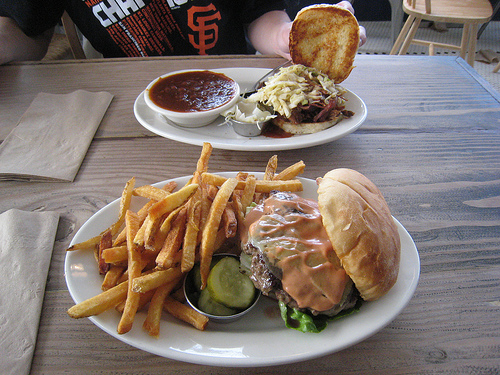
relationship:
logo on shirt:
[185, 3, 224, 58] [21, 0, 283, 58]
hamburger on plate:
[241, 169, 402, 332] [63, 171, 421, 366]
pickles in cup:
[210, 256, 254, 323] [181, 252, 263, 323]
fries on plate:
[66, 176, 185, 341] [63, 171, 421, 366]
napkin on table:
[0, 202, 63, 374] [367, 42, 496, 374]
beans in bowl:
[169, 79, 193, 94] [142, 67, 241, 129]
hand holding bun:
[271, 1, 368, 64] [288, 4, 359, 84]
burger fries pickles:
[241, 169, 402, 332] [210, 256, 254, 323]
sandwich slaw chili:
[257, 4, 360, 136] [149, 71, 232, 113]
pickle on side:
[210, 256, 254, 323] [181, 252, 263, 323]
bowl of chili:
[142, 67, 241, 129] [149, 71, 232, 113]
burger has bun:
[241, 169, 402, 332] [317, 166, 402, 302]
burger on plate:
[241, 169, 402, 332] [63, 171, 421, 366]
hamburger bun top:
[241, 169, 402, 332] [317, 166, 402, 302]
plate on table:
[63, 171, 421, 366] [367, 42, 496, 374]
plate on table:
[132, 63, 369, 154] [367, 42, 496, 374]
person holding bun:
[248, 1, 374, 82] [288, 4, 359, 84]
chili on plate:
[149, 71, 232, 113] [132, 63, 369, 154]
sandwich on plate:
[257, 4, 360, 136] [132, 63, 369, 154]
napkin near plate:
[0, 202, 63, 374] [63, 171, 421, 366]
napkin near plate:
[2, 89, 114, 183] [132, 63, 369, 154]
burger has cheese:
[241, 169, 402, 332] [250, 211, 284, 249]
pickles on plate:
[210, 256, 254, 323] [63, 171, 421, 366]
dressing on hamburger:
[288, 258, 337, 289] [241, 169, 402, 332]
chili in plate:
[167, 79, 217, 106] [132, 63, 369, 154]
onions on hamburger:
[262, 255, 284, 281] [241, 169, 402, 332]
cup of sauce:
[230, 115, 268, 140] [160, 75, 227, 105]